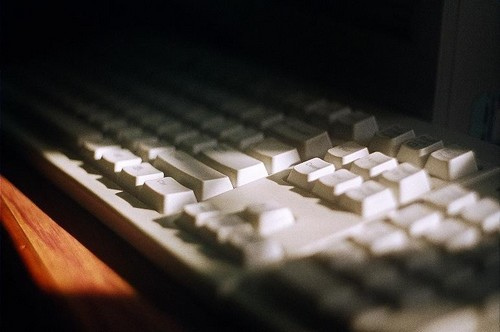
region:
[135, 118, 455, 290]
Light shines on the keyboard.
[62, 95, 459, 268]
The keyboard has several keys.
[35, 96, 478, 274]
The keyboard is white.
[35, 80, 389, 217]
The keys are in a row.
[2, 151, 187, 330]
The keyboard is on a table.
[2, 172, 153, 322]
Light is shining on the table.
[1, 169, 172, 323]
The table is made of wood.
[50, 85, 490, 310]
The keyboard is made of plastic.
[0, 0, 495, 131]
It is dark behind the keyboard.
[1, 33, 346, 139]
Part of the keyboard is hidden in the dark.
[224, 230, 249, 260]
part of a button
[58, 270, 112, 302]
edge of a shade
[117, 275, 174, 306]
edge of a shade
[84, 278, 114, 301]
part of a shade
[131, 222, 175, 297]
edge of a keyboard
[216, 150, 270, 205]
edge of a button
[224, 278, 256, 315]
part of a keyboard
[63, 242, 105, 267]
part of a table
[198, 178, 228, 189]
edge of a button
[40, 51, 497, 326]
The keyboard is white.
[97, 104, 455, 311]
The keyboard has keys.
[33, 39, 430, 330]
The keyboard is on the table.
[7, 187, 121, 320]
The table is wood.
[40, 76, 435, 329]
The sun is shinging through.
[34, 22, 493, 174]
The shadow is dark.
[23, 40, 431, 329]
Two shadows are on the keyboard.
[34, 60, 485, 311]
The keyboard is clean.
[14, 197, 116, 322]
The table is small.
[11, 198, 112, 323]
The table is brown.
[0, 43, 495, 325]
keyboard is white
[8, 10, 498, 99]
part of keyboard is in the dark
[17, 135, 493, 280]
sunshine on keyboard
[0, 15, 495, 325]
keyboard is on a wood table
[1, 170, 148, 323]
table is brown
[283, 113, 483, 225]
nine keys in keyboard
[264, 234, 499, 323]
a shadow cast on keyboard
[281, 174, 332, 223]
space on a keyboard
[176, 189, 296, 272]
four keys on a keyboard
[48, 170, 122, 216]
shadow of keys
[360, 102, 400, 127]
edge of a key board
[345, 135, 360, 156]
button on a key board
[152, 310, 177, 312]
part of a table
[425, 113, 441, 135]
upper part of the key board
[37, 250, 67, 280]
edge of a table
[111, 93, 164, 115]
dark side of the key board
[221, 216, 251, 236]
arrows of the key board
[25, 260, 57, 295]
edge of a table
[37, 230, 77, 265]
side of the table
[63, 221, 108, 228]
top of a table